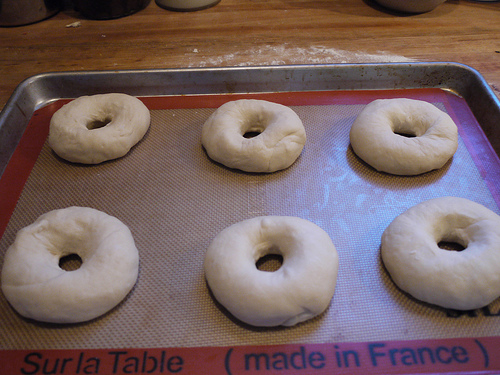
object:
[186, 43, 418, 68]
flour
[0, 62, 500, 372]
cookie sheet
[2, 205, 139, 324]
dough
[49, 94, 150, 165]
dough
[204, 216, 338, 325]
dough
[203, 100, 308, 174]
dough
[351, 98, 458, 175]
dough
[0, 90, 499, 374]
mat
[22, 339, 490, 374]
writing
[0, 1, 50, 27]
cannister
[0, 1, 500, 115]
table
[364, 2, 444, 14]
cannister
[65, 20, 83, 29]
crumb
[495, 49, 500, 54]
marks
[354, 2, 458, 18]
shadow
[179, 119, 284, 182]
shadow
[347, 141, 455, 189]
shadow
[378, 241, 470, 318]
shadow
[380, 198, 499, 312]
dough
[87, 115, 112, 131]
hole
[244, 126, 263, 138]
hole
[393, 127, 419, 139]
hole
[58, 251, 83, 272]
hole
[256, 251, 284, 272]
hole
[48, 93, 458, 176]
row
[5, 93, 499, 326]
food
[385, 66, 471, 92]
brown spots